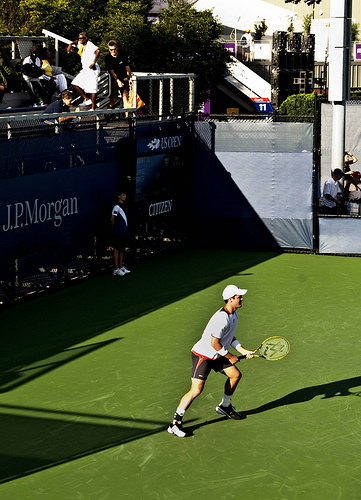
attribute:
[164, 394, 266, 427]
tennis shoes — black, white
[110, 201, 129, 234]
shirt — white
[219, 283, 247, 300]
cap — white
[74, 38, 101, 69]
shirt — white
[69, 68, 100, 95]
shorts — white